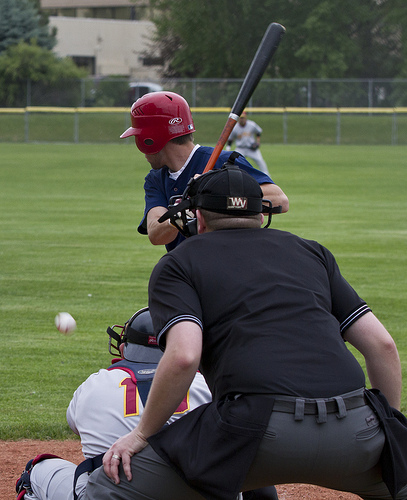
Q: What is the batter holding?
A: A baseball bat.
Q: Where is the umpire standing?
A: Behind the catcher.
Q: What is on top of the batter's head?
A: A helmet.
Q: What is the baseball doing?
A: Flying through the air.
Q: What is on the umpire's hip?
A: A black pouch.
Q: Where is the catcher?
A: Behind the batter.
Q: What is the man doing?
A: He is an umpire.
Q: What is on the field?
A: Green grass.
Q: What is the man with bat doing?
A: Hitting the ball.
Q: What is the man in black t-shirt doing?
A: Umpiring the the game.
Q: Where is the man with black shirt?
A: Behind the baseball players.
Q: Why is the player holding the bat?
A: To hit the ball.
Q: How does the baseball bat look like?
A: Black, white, and orange.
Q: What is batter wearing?
A: A blue and white top.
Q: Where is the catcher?
A: Squatting down.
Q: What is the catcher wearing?
A: A uniform.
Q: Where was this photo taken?
A: A baseball field.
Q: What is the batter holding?
A: A bat.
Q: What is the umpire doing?
A: Bending over.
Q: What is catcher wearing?
A: A grey and red uniform.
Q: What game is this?
A: Baseball.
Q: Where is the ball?
A: In the air.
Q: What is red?
A: Helmet.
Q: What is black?
A: Shirt.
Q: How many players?
A: Four.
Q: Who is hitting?
A: Boy.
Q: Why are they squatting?
A: To watch the ball.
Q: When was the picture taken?
A: Daytime.